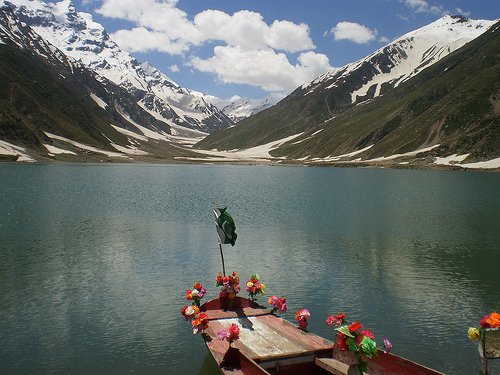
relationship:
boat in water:
[199, 292, 453, 374] [0, 161, 499, 374]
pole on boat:
[216, 238, 231, 276] [199, 292, 453, 374]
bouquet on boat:
[186, 284, 206, 303] [199, 292, 453, 374]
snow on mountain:
[400, 15, 496, 59] [192, 12, 499, 169]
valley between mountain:
[157, 111, 238, 160] [192, 12, 499, 169]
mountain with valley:
[192, 12, 499, 169] [157, 111, 238, 160]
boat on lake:
[198, 296, 447, 375] [1, 162, 497, 373]